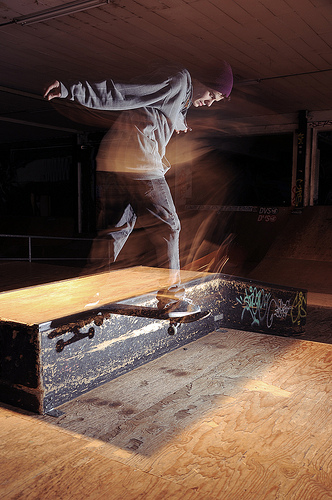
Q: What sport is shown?
A: Skateboarding.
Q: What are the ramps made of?
A: Wood.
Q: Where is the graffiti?
A: On ramps.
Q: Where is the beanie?
A: On boys head.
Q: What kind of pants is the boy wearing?
A: Jeans.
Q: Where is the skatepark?
A: Inside a building.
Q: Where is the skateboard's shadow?
A: On ramp.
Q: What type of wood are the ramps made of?
A: Plywood.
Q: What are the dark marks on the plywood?
A: Grain.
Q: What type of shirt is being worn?
A: Sweatshirt.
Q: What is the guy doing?
A: Skateboarding.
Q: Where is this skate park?
A: In a building.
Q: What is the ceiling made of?
A: Wood.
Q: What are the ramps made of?
A: Wood.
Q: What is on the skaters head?
A: Hat.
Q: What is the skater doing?
A: A trick.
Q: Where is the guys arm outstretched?
A: Behind him.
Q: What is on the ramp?
A: Graffiti.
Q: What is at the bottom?
A: The floor.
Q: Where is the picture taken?
A: Skatepark.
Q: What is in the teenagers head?
A: Hat.